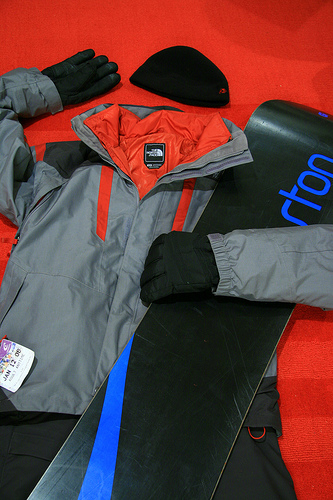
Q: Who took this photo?
A: A professional photographer.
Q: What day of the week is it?
A: Monday.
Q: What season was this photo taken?
A: Winter.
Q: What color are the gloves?
A: Black.